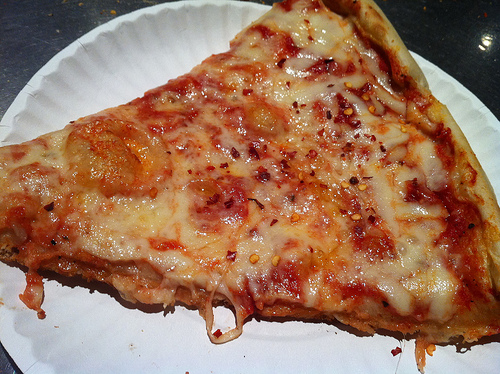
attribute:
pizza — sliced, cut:
[3, 1, 500, 343]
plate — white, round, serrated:
[2, 1, 500, 373]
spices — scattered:
[344, 108, 353, 115]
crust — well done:
[321, 1, 499, 334]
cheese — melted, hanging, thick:
[1, 2, 471, 343]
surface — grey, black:
[2, 2, 499, 373]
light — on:
[479, 33, 492, 53]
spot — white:
[315, 23, 336, 48]